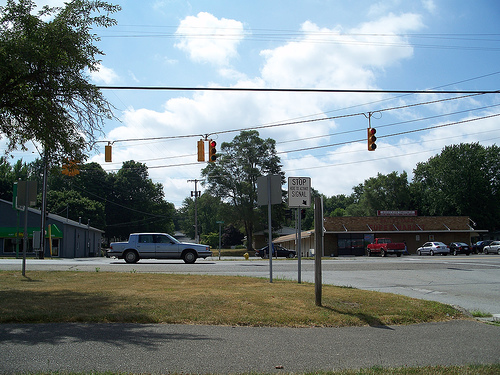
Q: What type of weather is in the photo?
A: It is cloudy.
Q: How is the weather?
A: It is cloudy.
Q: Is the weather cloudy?
A: Yes, it is cloudy.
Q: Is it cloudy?
A: Yes, it is cloudy.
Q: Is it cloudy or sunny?
A: It is cloudy.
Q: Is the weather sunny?
A: No, it is cloudy.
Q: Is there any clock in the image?
A: No, there are no clocks.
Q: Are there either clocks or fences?
A: No, there are no clocks or fences.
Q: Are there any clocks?
A: No, there are no clocks.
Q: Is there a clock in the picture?
A: No, there are no clocks.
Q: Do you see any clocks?
A: No, there are no clocks.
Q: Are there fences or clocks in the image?
A: No, there are no clocks or fences.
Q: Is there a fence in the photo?
A: No, there are no fences.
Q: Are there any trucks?
A: Yes, there is a truck.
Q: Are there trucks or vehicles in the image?
A: Yes, there is a truck.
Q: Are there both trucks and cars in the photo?
A: Yes, there are both a truck and a car.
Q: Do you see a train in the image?
A: No, there are no trains.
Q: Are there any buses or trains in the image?
A: No, there are no trains or buses.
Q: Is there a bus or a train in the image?
A: No, there are no trains or buses.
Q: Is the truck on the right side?
A: Yes, the truck is on the right of the image.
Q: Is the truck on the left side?
A: No, the truck is on the right of the image.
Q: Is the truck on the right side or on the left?
A: The truck is on the right of the image.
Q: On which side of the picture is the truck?
A: The truck is on the right of the image.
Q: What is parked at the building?
A: The truck is parked at the building.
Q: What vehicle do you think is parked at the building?
A: The vehicle is a truck.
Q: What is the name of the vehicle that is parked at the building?
A: The vehicle is a truck.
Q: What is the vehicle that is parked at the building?
A: The vehicle is a truck.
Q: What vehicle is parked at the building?
A: The vehicle is a truck.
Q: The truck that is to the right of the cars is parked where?
A: The truck is parked at the building.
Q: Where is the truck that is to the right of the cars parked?
A: The truck is parked at the building.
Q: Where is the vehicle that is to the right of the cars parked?
A: The truck is parked at the building.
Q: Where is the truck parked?
A: The truck is parked at the building.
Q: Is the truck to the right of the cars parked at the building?
A: Yes, the truck is parked at the building.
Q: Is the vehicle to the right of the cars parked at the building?
A: Yes, the truck is parked at the building.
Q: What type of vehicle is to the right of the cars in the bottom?
A: The vehicle is a truck.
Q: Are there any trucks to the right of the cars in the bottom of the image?
A: Yes, there is a truck to the right of the cars.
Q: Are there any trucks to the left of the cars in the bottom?
A: No, the truck is to the right of the cars.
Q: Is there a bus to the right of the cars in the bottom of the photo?
A: No, there is a truck to the right of the cars.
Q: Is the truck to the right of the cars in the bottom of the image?
A: Yes, the truck is to the right of the cars.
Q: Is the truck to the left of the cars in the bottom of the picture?
A: No, the truck is to the right of the cars.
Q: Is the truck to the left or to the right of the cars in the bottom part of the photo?
A: The truck is to the right of the cars.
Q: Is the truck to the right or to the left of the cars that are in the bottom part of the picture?
A: The truck is to the right of the cars.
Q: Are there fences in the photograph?
A: No, there are no fences.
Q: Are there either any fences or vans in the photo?
A: No, there are no fences or vans.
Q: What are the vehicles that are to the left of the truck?
A: The vehicles are cars.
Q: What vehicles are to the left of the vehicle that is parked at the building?
A: The vehicles are cars.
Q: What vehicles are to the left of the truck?
A: The vehicles are cars.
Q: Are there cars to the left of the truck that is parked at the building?
A: Yes, there are cars to the left of the truck.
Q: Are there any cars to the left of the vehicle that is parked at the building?
A: Yes, there are cars to the left of the truck.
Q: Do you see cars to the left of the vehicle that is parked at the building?
A: Yes, there are cars to the left of the truck.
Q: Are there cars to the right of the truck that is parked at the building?
A: No, the cars are to the left of the truck.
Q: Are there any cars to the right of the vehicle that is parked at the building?
A: No, the cars are to the left of the truck.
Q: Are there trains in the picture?
A: No, there are no trains.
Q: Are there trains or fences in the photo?
A: No, there are no trains or fences.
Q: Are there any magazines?
A: No, there are no magazines.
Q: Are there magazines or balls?
A: No, there are no magazines or balls.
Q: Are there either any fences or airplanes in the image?
A: No, there are no fences or airplanes.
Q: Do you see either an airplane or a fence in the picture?
A: No, there are no fences or airplanes.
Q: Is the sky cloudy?
A: Yes, the sky is cloudy.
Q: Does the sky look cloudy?
A: Yes, the sky is cloudy.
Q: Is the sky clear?
A: No, the sky is cloudy.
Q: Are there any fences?
A: No, there are no fences.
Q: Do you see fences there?
A: No, there are no fences.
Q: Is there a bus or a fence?
A: No, there are no fences or buses.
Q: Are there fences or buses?
A: No, there are no fences or buses.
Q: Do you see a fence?
A: No, there are no fences.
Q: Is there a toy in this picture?
A: No, there are no toys.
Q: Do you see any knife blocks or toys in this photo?
A: No, there are no toys or knife blocks.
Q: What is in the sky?
A: The clouds are in the sky.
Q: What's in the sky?
A: The clouds are in the sky.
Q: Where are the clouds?
A: The clouds are in the sky.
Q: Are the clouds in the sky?
A: Yes, the clouds are in the sky.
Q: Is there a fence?
A: No, there are no fences.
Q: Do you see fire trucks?
A: No, there are no fire trucks.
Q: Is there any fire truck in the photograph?
A: No, there are no fire trucks.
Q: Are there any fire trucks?
A: No, there are no fire trucks.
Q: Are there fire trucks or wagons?
A: No, there are no fire trucks or wagons.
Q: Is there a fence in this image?
A: No, there are no fences.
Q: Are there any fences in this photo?
A: No, there are no fences.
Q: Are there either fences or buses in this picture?
A: No, there are no fences or buses.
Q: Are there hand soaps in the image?
A: No, there are no hand soaps.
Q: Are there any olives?
A: No, there are no olives.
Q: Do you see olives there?
A: No, there are no olives.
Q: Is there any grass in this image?
A: Yes, there is grass.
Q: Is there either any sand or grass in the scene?
A: Yes, there is grass.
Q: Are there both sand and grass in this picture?
A: No, there is grass but no sand.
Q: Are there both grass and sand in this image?
A: No, there is grass but no sand.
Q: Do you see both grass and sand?
A: No, there is grass but no sand.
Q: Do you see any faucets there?
A: No, there are no faucets.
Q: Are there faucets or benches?
A: No, there are no faucets or benches.